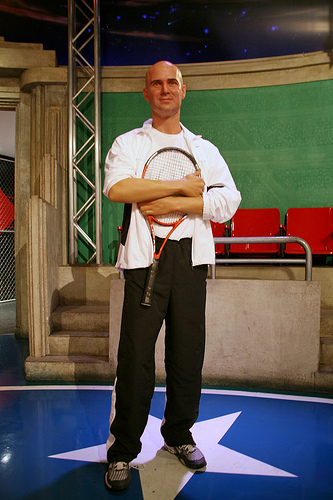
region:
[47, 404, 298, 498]
a white star on ground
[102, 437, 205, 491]
a pair of sneakers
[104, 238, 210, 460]
a black and white pair of sweatpants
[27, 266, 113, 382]
a small stair case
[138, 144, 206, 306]
a red tennis racket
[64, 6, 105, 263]
a silver metal tower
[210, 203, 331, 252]
the red seats in rear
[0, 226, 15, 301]
a fence along the side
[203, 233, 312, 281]
a metal railing on front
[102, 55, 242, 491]
a man on the star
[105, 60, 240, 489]
Andre Agassi standing on a white star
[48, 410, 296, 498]
white star on a blue flor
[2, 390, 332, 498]
shiny blue floor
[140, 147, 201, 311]
red and black tennis racket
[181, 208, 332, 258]
red bleacher seats by green wall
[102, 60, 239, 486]
tennis player hugging a tennis racket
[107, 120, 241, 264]
a white jacket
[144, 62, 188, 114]
a bald head on the man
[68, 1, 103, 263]
a silver pole behind the man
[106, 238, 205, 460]
black warm-up pants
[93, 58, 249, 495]
andre agassi holding racket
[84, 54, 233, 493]
tennis pro holding tennis racket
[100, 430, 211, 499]
men's athletic foot wear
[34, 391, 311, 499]
white star on blue floor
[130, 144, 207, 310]
red black and silver tennis racket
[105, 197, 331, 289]
row of red seats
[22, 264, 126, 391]
stone steps in background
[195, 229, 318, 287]
silver hand rail behind tennis pro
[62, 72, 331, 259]
green wall in background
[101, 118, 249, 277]
men's white zipper shirt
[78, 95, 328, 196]
WALL IN BACKGROUND IS GREEN IN COLOR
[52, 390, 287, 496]
A WHITE STAR IS ON THE FLOOR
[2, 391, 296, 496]
MAIN COLOR OF FLOOR IS BLUE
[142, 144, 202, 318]
MAN IS HOLDING A TENNIS RACKET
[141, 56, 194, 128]
MAN HAS NO HAIR ON HIS HEAD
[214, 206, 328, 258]
CHAIRS IN BACKGROUND ARE RED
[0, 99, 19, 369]
DOOR WAY IS TO THE LEFT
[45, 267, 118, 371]
STEPS ARE LOCATED TO THE LEFT BEHIND THE MAN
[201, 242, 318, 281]
METAL RAILING IS ON TOP OF WALL BEHIND THE MAN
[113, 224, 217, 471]
MAN IS WEARING BLACK PANTS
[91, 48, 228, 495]
This is Andre Aggasi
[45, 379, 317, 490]
He is standing on a star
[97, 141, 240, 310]
He is holding a tennis racket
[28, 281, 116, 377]
Three stone steps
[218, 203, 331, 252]
Several red chairs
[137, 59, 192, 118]
His head is bald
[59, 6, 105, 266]
Tall metal structure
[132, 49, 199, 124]
He is looking at the camera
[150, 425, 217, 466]
His left foot is entirely on the star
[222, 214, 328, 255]
The red chairs have armrests